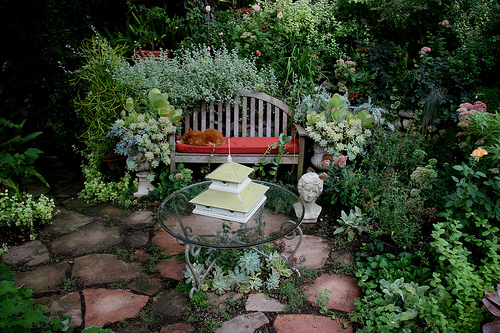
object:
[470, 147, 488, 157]
flower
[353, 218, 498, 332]
bush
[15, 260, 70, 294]
rock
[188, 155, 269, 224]
decoration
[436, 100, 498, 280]
vegetation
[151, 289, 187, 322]
stone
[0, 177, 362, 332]
walkway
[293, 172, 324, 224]
bust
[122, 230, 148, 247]
rock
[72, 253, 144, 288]
rock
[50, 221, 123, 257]
rock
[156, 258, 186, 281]
rock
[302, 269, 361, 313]
rock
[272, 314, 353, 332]
rock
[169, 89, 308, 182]
bench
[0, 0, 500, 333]
garden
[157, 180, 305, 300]
rable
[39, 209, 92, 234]
rock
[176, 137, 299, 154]
cushion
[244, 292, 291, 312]
rock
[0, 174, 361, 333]
ground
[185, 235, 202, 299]
legs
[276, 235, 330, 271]
rock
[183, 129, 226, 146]
animal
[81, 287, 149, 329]
rock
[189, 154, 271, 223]
bird house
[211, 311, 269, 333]
rock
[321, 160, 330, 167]
flowers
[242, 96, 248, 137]
slat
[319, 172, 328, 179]
flowers